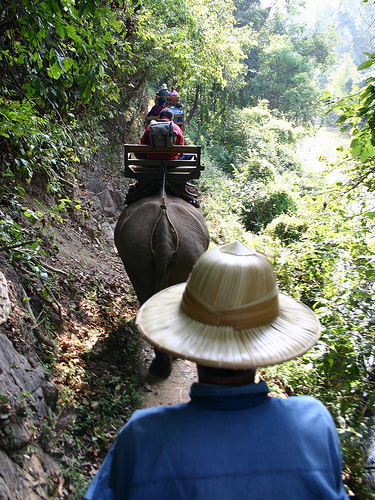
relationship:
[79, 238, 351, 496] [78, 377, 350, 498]
person wearing shirt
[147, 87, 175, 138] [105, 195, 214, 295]
people on elephant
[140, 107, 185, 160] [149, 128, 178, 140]
people wearing backpack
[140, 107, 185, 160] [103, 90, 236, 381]
people riding elephant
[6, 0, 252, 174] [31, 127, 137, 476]
foliage along path